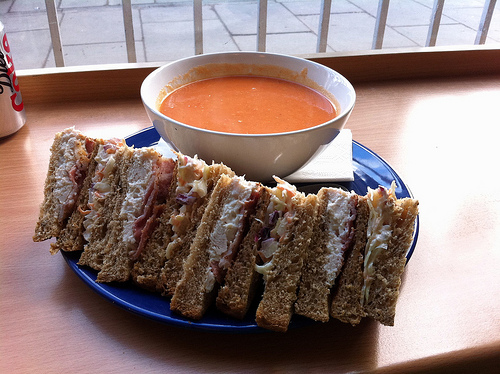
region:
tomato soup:
[186, 77, 293, 118]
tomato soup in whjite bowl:
[156, 57, 358, 157]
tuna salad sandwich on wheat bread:
[48, 141, 89, 243]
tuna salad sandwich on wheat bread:
[81, 140, 115, 261]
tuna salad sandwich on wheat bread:
[119, 157, 149, 278]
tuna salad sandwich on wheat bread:
[192, 176, 246, 316]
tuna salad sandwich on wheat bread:
[249, 189, 289, 314]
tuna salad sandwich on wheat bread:
[279, 199, 314, 340]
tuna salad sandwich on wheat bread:
[318, 183, 349, 320]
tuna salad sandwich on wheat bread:
[361, 191, 412, 329]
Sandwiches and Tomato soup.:
[34, 50, 420, 333]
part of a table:
[449, 51, 461, 63]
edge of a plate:
[221, 300, 228, 310]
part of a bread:
[213, 265, 251, 292]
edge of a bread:
[320, 265, 337, 301]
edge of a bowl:
[238, 99, 251, 161]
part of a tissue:
[318, 160, 338, 183]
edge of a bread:
[262, 293, 277, 328]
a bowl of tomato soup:
[141, 56, 383, 151]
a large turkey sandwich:
[18, 131, 445, 332]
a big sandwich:
[25, 128, 410, 337]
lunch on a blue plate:
[41, 55, 393, 341]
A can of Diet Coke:
[0, 18, 29, 136]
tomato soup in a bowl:
[133, 43, 375, 161]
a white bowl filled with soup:
[145, 50, 382, 173]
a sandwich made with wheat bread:
[20, 123, 415, 342]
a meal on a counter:
[37, 64, 497, 365]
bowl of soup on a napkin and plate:
[135, 25, 373, 172]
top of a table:
[480, 312, 491, 327]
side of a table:
[347, 339, 362, 365]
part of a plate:
[374, 166, 379, 181]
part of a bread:
[113, 202, 142, 282]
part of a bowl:
[252, 145, 261, 162]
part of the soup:
[223, 103, 229, 113]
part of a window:
[409, 57, 420, 75]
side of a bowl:
[271, 138, 294, 167]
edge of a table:
[409, 338, 420, 363]